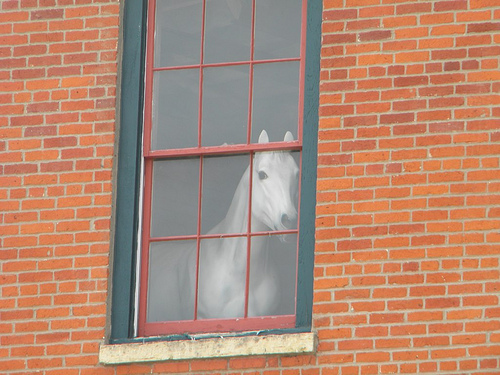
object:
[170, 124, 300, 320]
horse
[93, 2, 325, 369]
window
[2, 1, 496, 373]
wall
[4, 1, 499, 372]
building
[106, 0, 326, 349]
frame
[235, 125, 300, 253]
head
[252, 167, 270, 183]
eye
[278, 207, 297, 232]
nose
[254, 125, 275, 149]
ear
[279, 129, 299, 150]
ear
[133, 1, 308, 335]
trim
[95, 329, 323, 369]
window sill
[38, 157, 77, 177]
brick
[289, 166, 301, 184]
eye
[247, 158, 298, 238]
face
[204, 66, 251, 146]
panel